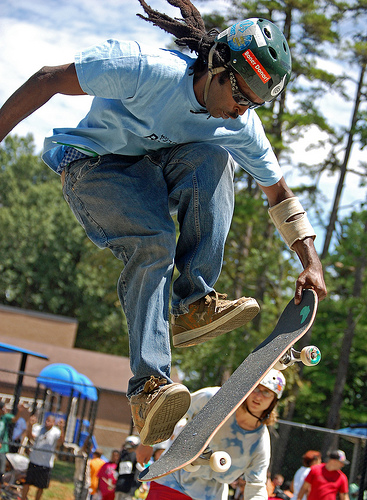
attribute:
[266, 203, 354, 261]
band — tan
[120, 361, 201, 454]
sneakers — brown, orange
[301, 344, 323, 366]
wheel — green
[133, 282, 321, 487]
skateboard — Black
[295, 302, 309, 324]
outline — green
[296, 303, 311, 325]
country — green